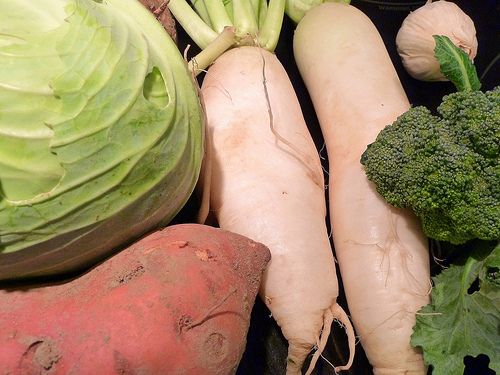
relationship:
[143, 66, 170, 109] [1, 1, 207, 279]
hole in leaf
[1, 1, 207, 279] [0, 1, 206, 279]
leaf of cabbage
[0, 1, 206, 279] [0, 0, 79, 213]
cabbage has curved edge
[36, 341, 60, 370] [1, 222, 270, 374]
dirt on sweet potato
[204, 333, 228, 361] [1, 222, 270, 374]
marking on sweet potato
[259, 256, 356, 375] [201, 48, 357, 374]
bottom of turnip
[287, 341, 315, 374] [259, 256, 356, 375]
root at bottom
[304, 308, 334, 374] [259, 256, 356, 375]
root at bottom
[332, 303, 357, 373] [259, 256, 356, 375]
root at bottom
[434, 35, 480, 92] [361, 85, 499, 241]
leaf of broccoli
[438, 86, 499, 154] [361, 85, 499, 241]
floret of broccoli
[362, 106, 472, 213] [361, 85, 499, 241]
floret of broccoli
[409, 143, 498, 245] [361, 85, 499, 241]
floret of broccoli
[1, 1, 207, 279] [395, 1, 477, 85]
leaf covering garlic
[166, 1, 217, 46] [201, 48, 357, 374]
stalk on top of turnip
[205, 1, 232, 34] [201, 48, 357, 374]
stalk on top of turnip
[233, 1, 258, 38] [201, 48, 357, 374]
stalk on top of turnip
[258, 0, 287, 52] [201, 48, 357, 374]
stalk on top of turnip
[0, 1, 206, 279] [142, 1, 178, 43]
cabbage with vegetable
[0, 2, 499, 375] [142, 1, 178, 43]
table beneath vegetable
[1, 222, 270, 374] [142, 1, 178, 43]
sweet potato in vegetable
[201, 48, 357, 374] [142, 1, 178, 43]
turnip in vegetable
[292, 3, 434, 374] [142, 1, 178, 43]
turnip in vegetable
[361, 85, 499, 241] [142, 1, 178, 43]
broccoli in vegetable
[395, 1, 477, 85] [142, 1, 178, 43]
garlic in vegetable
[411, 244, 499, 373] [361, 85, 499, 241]
leaf of broccoli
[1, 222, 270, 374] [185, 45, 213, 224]
sweet potato with root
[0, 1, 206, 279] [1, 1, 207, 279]
cabbage with leaf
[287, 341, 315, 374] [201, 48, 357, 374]
root of turnip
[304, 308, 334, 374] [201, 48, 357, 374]
root of turnip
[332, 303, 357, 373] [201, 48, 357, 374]
root of turnip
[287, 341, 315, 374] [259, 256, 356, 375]
root on bottom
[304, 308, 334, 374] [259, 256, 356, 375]
root on bottom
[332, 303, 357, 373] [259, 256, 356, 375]
root on bottom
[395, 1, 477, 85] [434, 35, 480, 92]
garlic under leaf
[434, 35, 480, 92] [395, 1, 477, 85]
leaf on top of garlic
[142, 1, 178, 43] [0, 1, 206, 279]
vegetable behind cabbage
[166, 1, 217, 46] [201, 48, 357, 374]
stalk on turnip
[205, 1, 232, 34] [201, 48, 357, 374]
stalk on turnip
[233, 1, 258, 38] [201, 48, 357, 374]
stalk on turnip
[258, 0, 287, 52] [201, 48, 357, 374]
stalk on turnip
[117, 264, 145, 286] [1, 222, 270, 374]
spot on sweet potato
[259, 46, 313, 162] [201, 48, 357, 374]
string on turnip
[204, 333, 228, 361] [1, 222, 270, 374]
marking in sweet potato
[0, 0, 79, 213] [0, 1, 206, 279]
curved edge of cabbage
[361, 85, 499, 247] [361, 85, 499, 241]
spores in broccoli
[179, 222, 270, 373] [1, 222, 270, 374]
edge of sweet potato